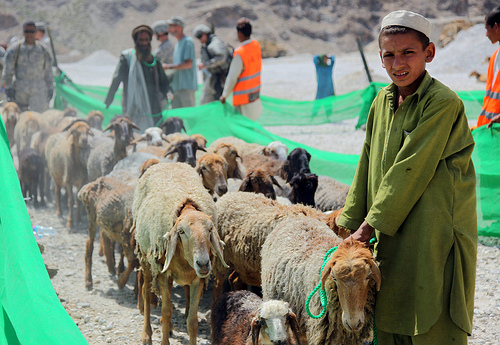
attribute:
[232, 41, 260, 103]
vest — orange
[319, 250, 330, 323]
rope — green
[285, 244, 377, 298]
wire —  green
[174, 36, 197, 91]
shirt —  blue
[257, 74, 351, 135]
fabric — green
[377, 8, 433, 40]
hat — white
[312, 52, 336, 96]
robe — blue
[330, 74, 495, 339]
shirt — green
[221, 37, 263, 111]
vest — orange 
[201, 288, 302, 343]
sheep — brown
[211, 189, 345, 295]
sheep — brown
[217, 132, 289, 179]
sheep — brown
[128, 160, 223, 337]
sheep — brown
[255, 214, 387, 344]
sheep — brown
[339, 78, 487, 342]
clothes — green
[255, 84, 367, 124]
fences — green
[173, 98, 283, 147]
fences — green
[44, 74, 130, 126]
fences — green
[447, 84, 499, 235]
fences — green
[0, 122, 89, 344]
fences — green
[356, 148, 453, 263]
clothes —  green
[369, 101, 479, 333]
cloths — blue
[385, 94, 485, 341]
robe — green